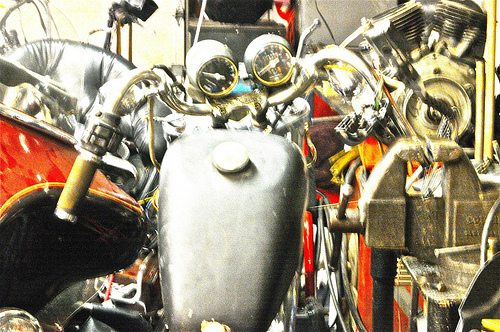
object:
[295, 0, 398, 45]
wall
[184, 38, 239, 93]
gauge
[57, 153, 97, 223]
handle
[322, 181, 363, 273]
handle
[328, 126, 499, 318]
vice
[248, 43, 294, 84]
speedometer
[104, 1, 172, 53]
parts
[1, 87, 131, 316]
parts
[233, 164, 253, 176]
shadow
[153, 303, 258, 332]
seat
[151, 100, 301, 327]
fuel tank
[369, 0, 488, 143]
engine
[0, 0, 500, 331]
bike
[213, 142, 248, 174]
cap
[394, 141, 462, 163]
teeth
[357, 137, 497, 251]
bench vise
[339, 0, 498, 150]
engine parts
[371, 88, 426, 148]
handlebar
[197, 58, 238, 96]
dials